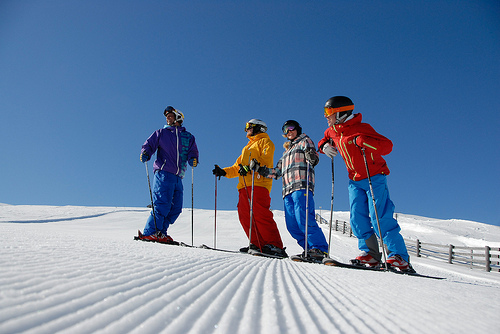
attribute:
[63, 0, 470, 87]
clouds — white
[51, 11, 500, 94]
sky — blue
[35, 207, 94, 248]
snow — white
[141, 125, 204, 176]
jacket — purple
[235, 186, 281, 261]
pats — red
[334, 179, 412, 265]
pants — bright blue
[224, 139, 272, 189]
jacket — yellow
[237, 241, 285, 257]
ski boots — orage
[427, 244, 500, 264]
fence — grey, gre, wood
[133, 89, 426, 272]
group — skiing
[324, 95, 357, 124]
helmet — black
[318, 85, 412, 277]
man — leaning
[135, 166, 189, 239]
pants — blue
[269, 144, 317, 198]
coat — plaid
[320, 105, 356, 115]
goggles — orage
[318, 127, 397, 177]
coat — red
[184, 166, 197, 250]
ski poles — dark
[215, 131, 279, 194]
coat — yellow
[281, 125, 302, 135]
goggles — clear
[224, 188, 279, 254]
pants — red